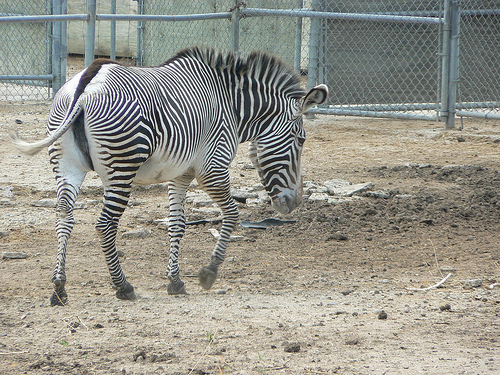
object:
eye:
[296, 137, 305, 144]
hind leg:
[92, 130, 156, 285]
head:
[247, 81, 328, 215]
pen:
[2, 1, 483, 371]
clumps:
[304, 210, 456, 263]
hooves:
[168, 279, 188, 295]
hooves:
[117, 286, 140, 301]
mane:
[263, 59, 309, 76]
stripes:
[123, 104, 131, 158]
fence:
[3, 0, 498, 132]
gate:
[442, 0, 499, 133]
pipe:
[0, 5, 440, 39]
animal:
[10, 45, 329, 307]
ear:
[301, 83, 329, 118]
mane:
[255, 55, 271, 95]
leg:
[48, 146, 92, 277]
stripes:
[208, 111, 234, 138]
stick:
[402, 268, 470, 304]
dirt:
[450, 345, 497, 374]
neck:
[226, 70, 285, 143]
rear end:
[7, 56, 109, 157]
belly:
[133, 153, 193, 193]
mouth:
[271, 193, 298, 214]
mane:
[220, 45, 233, 102]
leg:
[93, 163, 139, 287]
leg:
[163, 180, 186, 297]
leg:
[192, 161, 242, 266]